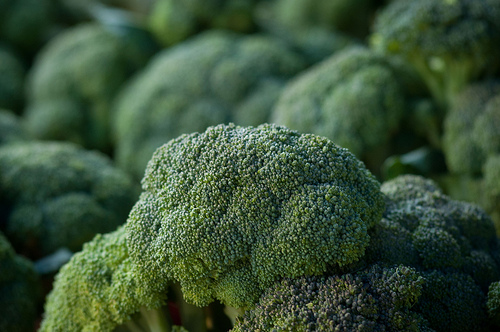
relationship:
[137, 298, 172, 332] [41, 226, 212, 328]
stalks of brocolli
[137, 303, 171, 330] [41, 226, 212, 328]
stalks of brocolli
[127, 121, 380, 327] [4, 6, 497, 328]
piece of vegetable